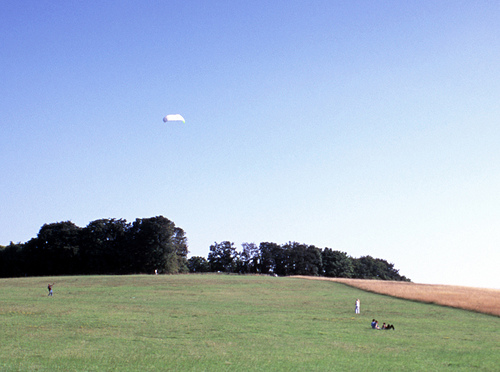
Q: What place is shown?
A: It is a field.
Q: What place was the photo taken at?
A: It was taken at the field.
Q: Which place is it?
A: It is a field.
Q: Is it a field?
A: Yes, it is a field.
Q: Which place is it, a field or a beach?
A: It is a field.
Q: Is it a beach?
A: No, it is a field.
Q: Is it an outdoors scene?
A: Yes, it is outdoors.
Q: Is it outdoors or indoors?
A: It is outdoors.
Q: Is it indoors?
A: No, it is outdoors.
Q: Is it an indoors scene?
A: No, it is outdoors.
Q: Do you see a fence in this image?
A: No, there are no fences.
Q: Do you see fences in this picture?
A: No, there are no fences.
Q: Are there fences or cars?
A: No, there are no fences or cars.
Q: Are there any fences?
A: No, there are no fences.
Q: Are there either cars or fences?
A: No, there are no fences or cars.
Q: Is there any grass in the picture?
A: Yes, there is grass.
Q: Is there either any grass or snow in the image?
A: Yes, there is grass.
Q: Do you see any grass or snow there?
A: Yes, there is grass.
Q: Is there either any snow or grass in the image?
A: Yes, there is grass.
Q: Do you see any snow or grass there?
A: Yes, there is grass.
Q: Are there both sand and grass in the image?
A: No, there is grass but no sand.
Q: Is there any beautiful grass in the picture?
A: Yes, there is beautiful grass.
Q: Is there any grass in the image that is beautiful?
A: Yes, there is grass that is beautiful.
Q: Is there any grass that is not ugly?
A: Yes, there is beautiful grass.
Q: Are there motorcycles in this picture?
A: No, there are no motorcycles.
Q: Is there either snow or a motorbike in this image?
A: No, there are no motorcycles or snow.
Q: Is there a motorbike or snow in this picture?
A: No, there are no motorcycles or snow.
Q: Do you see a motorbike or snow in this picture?
A: No, there are no motorcycles or snow.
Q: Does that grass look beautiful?
A: Yes, the grass is beautiful.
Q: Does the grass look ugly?
A: No, the grass is beautiful.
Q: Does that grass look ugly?
A: No, the grass is beautiful.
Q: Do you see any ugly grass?
A: No, there is grass but it is beautiful.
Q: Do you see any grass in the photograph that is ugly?
A: No, there is grass but it is beautiful.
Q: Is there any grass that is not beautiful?
A: No, there is grass but it is beautiful.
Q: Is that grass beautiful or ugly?
A: The grass is beautiful.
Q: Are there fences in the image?
A: No, there are no fences.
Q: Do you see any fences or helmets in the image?
A: No, there are no fences or helmets.